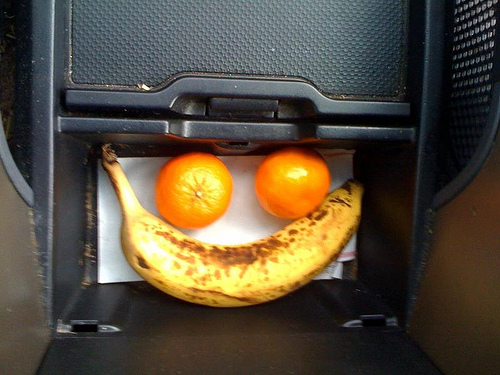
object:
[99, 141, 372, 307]
fruits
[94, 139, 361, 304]
smile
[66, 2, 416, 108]
covering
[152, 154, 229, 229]
orange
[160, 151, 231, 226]
rind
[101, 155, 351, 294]
paper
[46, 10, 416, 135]
compartment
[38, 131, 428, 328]
bottom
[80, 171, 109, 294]
debris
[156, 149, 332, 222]
oranges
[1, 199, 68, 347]
carpetting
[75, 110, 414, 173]
guard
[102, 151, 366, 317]
banana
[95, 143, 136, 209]
stem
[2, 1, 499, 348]
box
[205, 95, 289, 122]
handle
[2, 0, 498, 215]
plastic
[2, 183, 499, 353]
wall